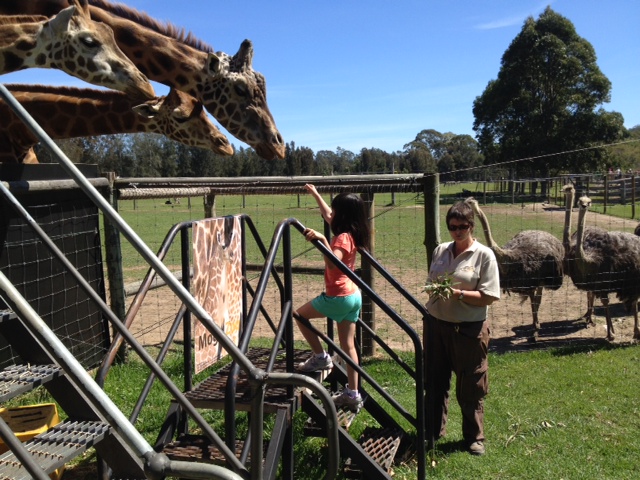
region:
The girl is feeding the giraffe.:
[215, 44, 375, 256]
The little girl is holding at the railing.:
[290, 178, 368, 264]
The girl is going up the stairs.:
[290, 174, 381, 422]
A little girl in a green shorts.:
[297, 176, 379, 334]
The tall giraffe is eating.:
[212, 39, 361, 238]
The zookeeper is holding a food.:
[420, 207, 495, 341]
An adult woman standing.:
[422, 188, 501, 469]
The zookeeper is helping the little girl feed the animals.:
[219, 67, 484, 330]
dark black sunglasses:
[443, 220, 473, 234]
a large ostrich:
[460, 195, 564, 328]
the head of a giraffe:
[133, 83, 233, 157]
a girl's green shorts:
[313, 293, 364, 325]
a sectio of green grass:
[374, 336, 638, 476]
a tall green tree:
[457, 4, 624, 187]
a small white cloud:
[475, 6, 539, 37]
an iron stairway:
[181, 338, 408, 473]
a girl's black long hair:
[330, 181, 369, 248]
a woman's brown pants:
[423, 317, 492, 444]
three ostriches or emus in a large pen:
[461, 182, 634, 350]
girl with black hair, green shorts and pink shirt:
[292, 181, 367, 416]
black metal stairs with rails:
[96, 211, 424, 472]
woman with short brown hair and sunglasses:
[410, 197, 499, 456]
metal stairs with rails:
[0, 81, 344, 475]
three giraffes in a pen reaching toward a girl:
[2, 0, 287, 171]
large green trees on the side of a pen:
[473, 8, 624, 189]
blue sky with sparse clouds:
[2, 1, 635, 151]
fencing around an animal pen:
[109, 184, 634, 340]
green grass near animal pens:
[6, 350, 633, 477]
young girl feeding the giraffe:
[289, 187, 375, 400]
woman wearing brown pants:
[414, 201, 507, 448]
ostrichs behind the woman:
[464, 177, 638, 334]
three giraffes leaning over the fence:
[2, 3, 284, 166]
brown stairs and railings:
[5, 83, 434, 469]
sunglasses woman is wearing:
[446, 219, 472, 235]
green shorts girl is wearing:
[312, 290, 362, 318]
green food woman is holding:
[420, 273, 453, 300]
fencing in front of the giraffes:
[9, 155, 222, 336]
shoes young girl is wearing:
[301, 348, 359, 406]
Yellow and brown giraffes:
[1, 7, 289, 165]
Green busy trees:
[53, 12, 638, 188]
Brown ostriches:
[447, 175, 637, 349]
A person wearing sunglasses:
[424, 193, 499, 462]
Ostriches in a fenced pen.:
[403, 176, 637, 377]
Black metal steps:
[133, 220, 436, 476]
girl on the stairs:
[290, 172, 378, 413]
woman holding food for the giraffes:
[411, 193, 496, 316]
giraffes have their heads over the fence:
[0, 0, 302, 168]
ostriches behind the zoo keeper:
[461, 170, 637, 344]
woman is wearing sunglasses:
[441, 201, 476, 239]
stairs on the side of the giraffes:
[0, 79, 346, 477]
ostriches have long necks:
[462, 178, 595, 257]